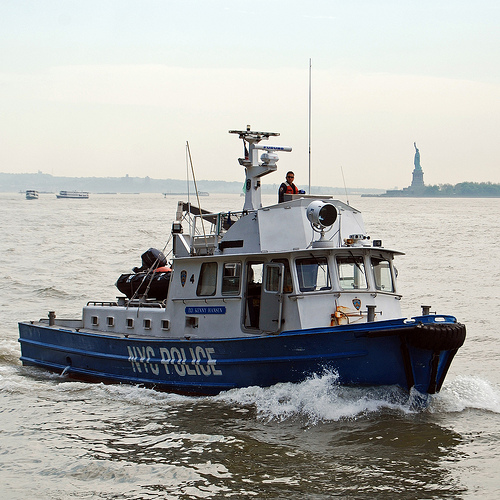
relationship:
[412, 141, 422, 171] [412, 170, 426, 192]
statue on pedestal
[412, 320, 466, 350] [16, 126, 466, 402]
tire on boat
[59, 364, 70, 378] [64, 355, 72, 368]
water coming from hole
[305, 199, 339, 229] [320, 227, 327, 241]
light mounted on pole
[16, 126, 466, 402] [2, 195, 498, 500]
boat moving on sea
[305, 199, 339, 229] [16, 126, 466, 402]
light mounted on boat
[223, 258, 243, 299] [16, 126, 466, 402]
window on boat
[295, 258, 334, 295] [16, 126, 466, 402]
window on boat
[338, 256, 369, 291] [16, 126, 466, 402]
window on boat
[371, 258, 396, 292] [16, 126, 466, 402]
window on boat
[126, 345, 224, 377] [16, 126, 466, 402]
sign on boat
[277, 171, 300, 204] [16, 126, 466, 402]
officer on boat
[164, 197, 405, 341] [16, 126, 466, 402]
cabin on boat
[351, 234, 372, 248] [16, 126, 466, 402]
horn mounted on boat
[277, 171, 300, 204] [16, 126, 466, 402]
officer piloting boat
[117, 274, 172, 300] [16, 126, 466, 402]
raft on boat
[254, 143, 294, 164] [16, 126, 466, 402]
radar on boat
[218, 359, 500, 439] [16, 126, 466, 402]
wave created by boat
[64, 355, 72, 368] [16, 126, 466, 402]
hole on boat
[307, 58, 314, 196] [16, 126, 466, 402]
aentenna on boat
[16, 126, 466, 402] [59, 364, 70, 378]
boat in water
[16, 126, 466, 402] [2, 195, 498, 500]
boat in sea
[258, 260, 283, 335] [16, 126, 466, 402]
door on boat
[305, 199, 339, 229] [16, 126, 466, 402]
light on boat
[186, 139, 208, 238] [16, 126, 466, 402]
pole on boat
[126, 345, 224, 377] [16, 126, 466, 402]
sign on blue boat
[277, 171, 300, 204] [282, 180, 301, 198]
officer standing in vest